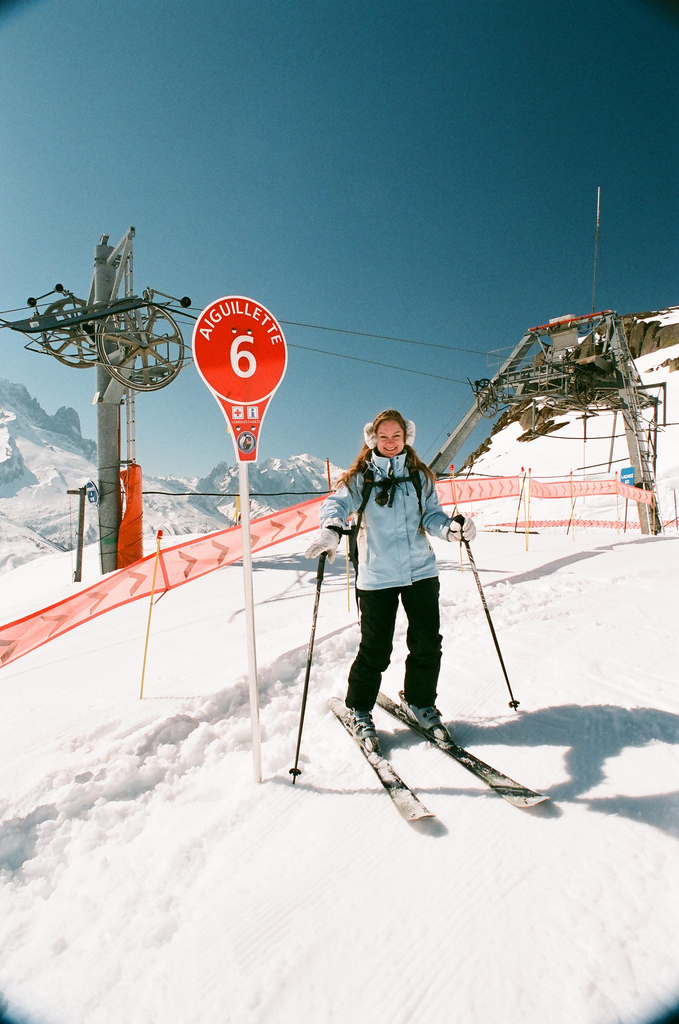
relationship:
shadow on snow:
[558, 700, 663, 777] [3, 379, 678, 982]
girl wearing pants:
[282, 379, 494, 762] [343, 574, 441, 714]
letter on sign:
[219, 302, 230, 316] [193, 298, 285, 464]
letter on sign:
[224, 296, 232, 314] [193, 298, 285, 464]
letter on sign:
[232, 297, 240, 313] [193, 298, 285, 464]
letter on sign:
[242, 295, 253, 316] [193, 298, 285, 464]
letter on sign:
[251, 306, 258, 315] [193, 298, 285, 464]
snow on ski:
[382, 759, 459, 871] [327, 681, 433, 834]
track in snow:
[19, 666, 262, 884] [12, 491, 657, 988]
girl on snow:
[305, 406, 477, 753] [3, 428, 678, 1016]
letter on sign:
[194, 325, 217, 337] [190, 281, 298, 456]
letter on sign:
[199, 314, 215, 331] [177, 286, 285, 447]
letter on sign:
[208, 306, 218, 321] [196, 281, 276, 461]